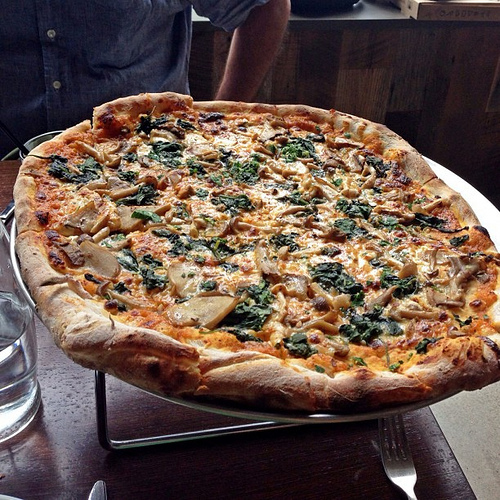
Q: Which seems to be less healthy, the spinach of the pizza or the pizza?
A: The pizza is less healthy than the spinach.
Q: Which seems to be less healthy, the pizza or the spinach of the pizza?
A: The pizza is less healthy than the spinach.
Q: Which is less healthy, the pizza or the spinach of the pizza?
A: The pizza is less healthy than the spinach.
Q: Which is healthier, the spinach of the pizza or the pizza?
A: The spinach is healthier than the pizza.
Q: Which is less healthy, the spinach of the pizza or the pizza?
A: The pizza is less healthy than the spinach.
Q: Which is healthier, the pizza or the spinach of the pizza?
A: The spinach is healthier than the pizza.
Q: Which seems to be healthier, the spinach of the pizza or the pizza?
A: The spinach is healthier than the pizza.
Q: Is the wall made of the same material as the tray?
A: Yes, both the wall and the tray are made of wood.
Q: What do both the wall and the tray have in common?
A: The material, both the wall and the tray are wooden.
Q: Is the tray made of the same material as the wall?
A: Yes, both the tray and the wall are made of wood.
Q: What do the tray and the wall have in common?
A: The material, both the tray and the wall are wooden.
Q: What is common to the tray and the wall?
A: The material, both the tray and the wall are wooden.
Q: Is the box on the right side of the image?
A: Yes, the box is on the right of the image.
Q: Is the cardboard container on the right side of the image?
A: Yes, the box is on the right of the image.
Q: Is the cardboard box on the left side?
A: No, the box is on the right of the image.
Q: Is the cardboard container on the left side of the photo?
A: No, the box is on the right of the image.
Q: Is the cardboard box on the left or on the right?
A: The box is on the right of the image.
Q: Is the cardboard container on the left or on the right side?
A: The box is on the right of the image.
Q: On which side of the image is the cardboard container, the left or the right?
A: The box is on the right of the image.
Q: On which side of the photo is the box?
A: The box is on the right of the image.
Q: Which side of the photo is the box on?
A: The box is on the right of the image.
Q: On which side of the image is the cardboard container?
A: The box is on the right of the image.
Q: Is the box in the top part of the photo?
A: Yes, the box is in the top of the image.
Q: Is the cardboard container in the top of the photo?
A: Yes, the box is in the top of the image.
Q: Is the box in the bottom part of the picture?
A: No, the box is in the top of the image.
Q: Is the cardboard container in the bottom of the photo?
A: No, the box is in the top of the image.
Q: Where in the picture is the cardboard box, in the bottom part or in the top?
A: The box is in the top of the image.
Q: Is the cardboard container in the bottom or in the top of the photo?
A: The box is in the top of the image.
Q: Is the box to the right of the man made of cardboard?
A: Yes, the box is made of cardboard.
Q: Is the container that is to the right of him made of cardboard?
A: Yes, the box is made of cardboard.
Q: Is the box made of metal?
A: No, the box is made of cardboard.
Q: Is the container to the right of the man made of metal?
A: No, the box is made of cardboard.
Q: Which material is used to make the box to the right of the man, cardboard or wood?
A: The box is made of cardboard.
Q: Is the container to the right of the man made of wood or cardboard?
A: The box is made of cardboard.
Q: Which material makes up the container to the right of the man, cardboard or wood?
A: The box is made of cardboard.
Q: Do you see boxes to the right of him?
A: Yes, there is a box to the right of the man.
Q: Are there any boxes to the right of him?
A: Yes, there is a box to the right of the man.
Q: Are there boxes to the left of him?
A: No, the box is to the right of the man.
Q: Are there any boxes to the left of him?
A: No, the box is to the right of the man.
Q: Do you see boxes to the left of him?
A: No, the box is to the right of the man.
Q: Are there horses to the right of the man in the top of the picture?
A: No, there is a box to the right of the man.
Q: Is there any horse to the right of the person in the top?
A: No, there is a box to the right of the man.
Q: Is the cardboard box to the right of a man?
A: Yes, the box is to the right of a man.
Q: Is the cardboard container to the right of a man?
A: Yes, the box is to the right of a man.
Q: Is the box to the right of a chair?
A: No, the box is to the right of a man.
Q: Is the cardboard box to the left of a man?
A: No, the box is to the right of a man.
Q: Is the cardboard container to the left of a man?
A: No, the box is to the right of a man.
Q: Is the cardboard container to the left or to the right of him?
A: The box is to the right of the man.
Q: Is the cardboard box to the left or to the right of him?
A: The box is to the right of the man.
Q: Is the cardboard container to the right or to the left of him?
A: The box is to the right of the man.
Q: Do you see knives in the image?
A: Yes, there is a knife.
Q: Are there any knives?
A: Yes, there is a knife.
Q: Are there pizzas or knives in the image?
A: Yes, there is a knife.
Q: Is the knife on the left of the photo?
A: Yes, the knife is on the left of the image.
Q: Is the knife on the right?
A: No, the knife is on the left of the image.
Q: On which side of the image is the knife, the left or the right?
A: The knife is on the left of the image.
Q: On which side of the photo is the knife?
A: The knife is on the left of the image.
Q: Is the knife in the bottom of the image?
A: Yes, the knife is in the bottom of the image.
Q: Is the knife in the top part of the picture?
A: No, the knife is in the bottom of the image.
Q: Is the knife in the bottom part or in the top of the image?
A: The knife is in the bottom of the image.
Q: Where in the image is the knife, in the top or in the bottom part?
A: The knife is in the bottom of the image.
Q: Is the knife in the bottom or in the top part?
A: The knife is in the bottom of the image.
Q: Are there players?
A: No, there are no players.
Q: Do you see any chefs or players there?
A: No, there are no players or chefs.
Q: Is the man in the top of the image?
A: Yes, the man is in the top of the image.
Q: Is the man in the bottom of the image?
A: No, the man is in the top of the image.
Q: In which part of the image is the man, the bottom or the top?
A: The man is in the top of the image.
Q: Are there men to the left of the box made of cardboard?
A: Yes, there is a man to the left of the box.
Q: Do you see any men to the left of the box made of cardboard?
A: Yes, there is a man to the left of the box.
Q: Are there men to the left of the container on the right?
A: Yes, there is a man to the left of the box.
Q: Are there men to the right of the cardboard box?
A: No, the man is to the left of the box.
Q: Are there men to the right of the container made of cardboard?
A: No, the man is to the left of the box.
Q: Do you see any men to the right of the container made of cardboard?
A: No, the man is to the left of the box.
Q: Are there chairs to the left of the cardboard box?
A: No, there is a man to the left of the box.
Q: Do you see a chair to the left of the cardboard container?
A: No, there is a man to the left of the box.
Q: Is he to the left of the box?
A: Yes, the man is to the left of the box.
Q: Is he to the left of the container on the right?
A: Yes, the man is to the left of the box.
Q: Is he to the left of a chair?
A: No, the man is to the left of the box.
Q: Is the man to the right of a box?
A: No, the man is to the left of a box.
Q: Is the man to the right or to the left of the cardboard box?
A: The man is to the left of the box.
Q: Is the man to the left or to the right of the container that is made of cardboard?
A: The man is to the left of the box.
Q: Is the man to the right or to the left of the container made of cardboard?
A: The man is to the left of the box.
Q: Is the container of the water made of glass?
A: Yes, the container is made of glass.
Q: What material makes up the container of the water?
A: The container is made of glass.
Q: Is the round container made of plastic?
A: No, the container is made of glass.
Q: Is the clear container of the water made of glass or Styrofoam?
A: The container is made of glass.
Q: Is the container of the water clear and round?
A: Yes, the container is clear and round.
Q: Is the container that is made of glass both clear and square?
A: No, the container is clear but round.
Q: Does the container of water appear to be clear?
A: Yes, the container is clear.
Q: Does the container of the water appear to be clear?
A: Yes, the container is clear.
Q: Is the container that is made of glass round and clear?
A: Yes, the container is round and clear.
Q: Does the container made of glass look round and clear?
A: Yes, the container is round and clear.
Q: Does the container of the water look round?
A: Yes, the container is round.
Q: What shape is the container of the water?
A: The container is round.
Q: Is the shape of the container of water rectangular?
A: No, the container is round.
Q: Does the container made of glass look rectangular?
A: No, the container is round.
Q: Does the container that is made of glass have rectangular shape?
A: No, the container is round.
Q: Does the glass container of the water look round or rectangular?
A: The container is round.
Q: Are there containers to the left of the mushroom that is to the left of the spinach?
A: Yes, there is a container to the left of the mushroom.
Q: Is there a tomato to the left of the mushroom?
A: No, there is a container to the left of the mushroom.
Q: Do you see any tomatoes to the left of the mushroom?
A: No, there is a container to the left of the mushroom.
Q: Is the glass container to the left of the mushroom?
A: Yes, the container is to the left of the mushroom.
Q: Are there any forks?
A: Yes, there is a fork.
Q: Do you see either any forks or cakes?
A: Yes, there is a fork.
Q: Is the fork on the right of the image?
A: Yes, the fork is on the right of the image.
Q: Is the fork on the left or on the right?
A: The fork is on the right of the image.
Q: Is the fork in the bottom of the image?
A: Yes, the fork is in the bottom of the image.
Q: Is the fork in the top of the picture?
A: No, the fork is in the bottom of the image.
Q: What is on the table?
A: The fork is on the table.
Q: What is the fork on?
A: The fork is on the table.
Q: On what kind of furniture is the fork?
A: The fork is on the table.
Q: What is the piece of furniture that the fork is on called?
A: The piece of furniture is a table.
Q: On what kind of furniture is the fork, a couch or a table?
A: The fork is on a table.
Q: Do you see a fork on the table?
A: Yes, there is a fork on the table.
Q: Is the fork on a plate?
A: No, the fork is on the table.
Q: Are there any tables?
A: Yes, there is a table.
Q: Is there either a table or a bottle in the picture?
A: Yes, there is a table.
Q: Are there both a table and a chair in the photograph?
A: No, there is a table but no chairs.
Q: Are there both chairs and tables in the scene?
A: No, there is a table but no chairs.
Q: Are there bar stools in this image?
A: No, there are no bar stools.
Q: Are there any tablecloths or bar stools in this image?
A: No, there are no bar stools or tablecloths.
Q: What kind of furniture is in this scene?
A: The furniture is a table.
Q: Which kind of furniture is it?
A: The piece of furniture is a table.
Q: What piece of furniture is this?
A: This is a table.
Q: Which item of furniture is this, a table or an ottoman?
A: This is a table.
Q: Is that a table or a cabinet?
A: That is a table.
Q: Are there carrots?
A: No, there are no carrots.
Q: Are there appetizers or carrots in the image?
A: No, there are no carrots or appetizers.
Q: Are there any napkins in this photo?
A: No, there are no napkins.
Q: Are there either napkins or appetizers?
A: No, there are no napkins or appetizers.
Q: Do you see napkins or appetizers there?
A: No, there are no napkins or appetizers.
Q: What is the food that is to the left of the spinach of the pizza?
A: The food is a mushroom.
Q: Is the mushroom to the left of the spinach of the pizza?
A: Yes, the mushroom is to the left of the spinach.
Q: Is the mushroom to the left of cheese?
A: No, the mushroom is to the left of the spinach.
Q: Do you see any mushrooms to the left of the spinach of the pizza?
A: Yes, there is a mushroom to the left of the spinach.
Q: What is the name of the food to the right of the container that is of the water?
A: The food is a mushroom.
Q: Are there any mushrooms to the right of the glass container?
A: Yes, there is a mushroom to the right of the container.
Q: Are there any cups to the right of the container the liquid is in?
A: No, there is a mushroom to the right of the container.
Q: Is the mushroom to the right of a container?
A: Yes, the mushroom is to the right of a container.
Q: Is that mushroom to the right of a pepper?
A: No, the mushroom is to the right of a container.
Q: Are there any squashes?
A: No, there are no squashes.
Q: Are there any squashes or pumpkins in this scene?
A: No, there are no squashes or pumpkins.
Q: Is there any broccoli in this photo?
A: No, there is no broccoli.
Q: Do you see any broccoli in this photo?
A: No, there is no broccoli.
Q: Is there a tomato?
A: No, there are no tomatoes.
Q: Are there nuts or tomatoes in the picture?
A: No, there are no tomatoes or nuts.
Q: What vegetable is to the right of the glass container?
A: The vegetable is spinach.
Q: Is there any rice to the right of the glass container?
A: No, there is spinach to the right of the container.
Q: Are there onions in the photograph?
A: No, there are no onions.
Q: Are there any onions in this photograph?
A: No, there are no onions.